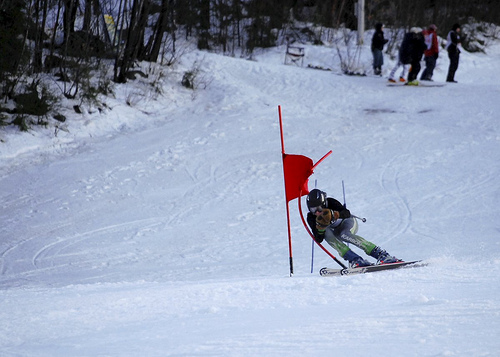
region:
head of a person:
[297, 180, 329, 221]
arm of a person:
[308, 205, 334, 247]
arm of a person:
[322, 196, 356, 216]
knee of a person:
[319, 221, 341, 238]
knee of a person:
[339, 228, 351, 235]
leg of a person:
[326, 238, 366, 263]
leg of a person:
[348, 230, 385, 262]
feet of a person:
[339, 255, 371, 272]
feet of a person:
[376, 253, 416, 270]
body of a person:
[366, 15, 399, 63]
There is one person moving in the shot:
[253, 90, 469, 305]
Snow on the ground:
[116, 265, 257, 351]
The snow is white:
[106, 250, 236, 322]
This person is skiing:
[253, 135, 459, 303]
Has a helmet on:
[287, 171, 342, 224]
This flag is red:
[256, 100, 323, 290]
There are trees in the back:
[4, 1, 499, 110]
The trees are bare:
[11, 8, 195, 110]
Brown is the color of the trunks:
[14, 14, 176, 104]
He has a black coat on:
[288, 190, 370, 245]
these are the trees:
[3, 2, 296, 135]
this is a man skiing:
[304, 184, 420, 274]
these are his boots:
[346, 248, 403, 268]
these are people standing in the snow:
[367, 19, 467, 86]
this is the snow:
[2, 25, 497, 354]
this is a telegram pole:
[356, 0, 365, 50]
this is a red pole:
[275, 102, 346, 280]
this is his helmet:
[305, 185, 327, 212]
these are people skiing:
[366, 18, 471, 88]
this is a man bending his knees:
[303, 185, 425, 284]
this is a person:
[300, 165, 400, 273]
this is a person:
[437, 22, 481, 83]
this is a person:
[417, 19, 446, 84]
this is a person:
[401, 20, 434, 90]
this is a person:
[359, 10, 393, 77]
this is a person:
[399, 17, 423, 87]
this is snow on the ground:
[210, 248, 268, 308]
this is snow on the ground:
[141, 132, 208, 199]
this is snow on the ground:
[399, 116, 466, 206]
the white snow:
[89, 227, 196, 327]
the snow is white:
[161, 283, 248, 347]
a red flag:
[285, 151, 312, 193]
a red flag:
[283, 153, 316, 200]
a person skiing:
[300, 186, 412, 266]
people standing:
[373, 25, 465, 83]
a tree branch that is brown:
[112, 26, 144, 78]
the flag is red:
[281, 147, 313, 199]